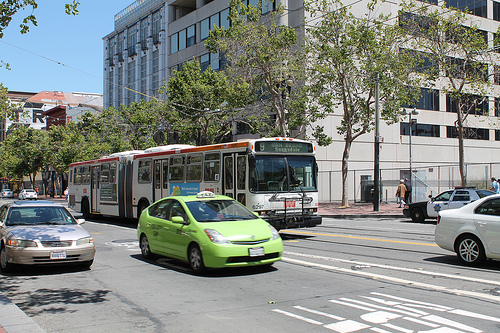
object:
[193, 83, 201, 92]
leaf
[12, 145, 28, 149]
leaf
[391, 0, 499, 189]
plant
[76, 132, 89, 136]
leaf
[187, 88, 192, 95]
leaf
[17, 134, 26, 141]
leaf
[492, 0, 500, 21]
window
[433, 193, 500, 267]
car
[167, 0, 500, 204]
building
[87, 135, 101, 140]
leaf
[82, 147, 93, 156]
leaf